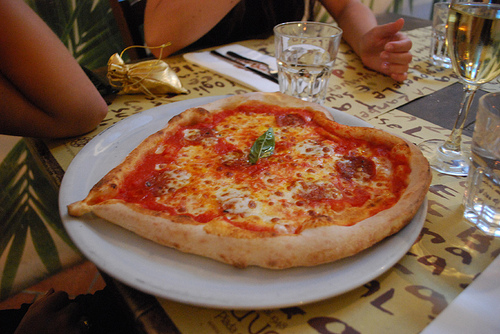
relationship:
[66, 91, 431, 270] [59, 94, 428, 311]
individual pizza on plate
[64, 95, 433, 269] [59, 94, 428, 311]
individual pizza on plate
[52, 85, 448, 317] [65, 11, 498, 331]
plate on top of table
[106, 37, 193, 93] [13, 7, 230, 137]
bag between arms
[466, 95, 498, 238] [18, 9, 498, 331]
glass on table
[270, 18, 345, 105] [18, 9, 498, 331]
glass on table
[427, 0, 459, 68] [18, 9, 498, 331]
glass on table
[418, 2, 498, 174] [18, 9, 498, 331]
glass on table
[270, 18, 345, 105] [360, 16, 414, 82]
glass on hand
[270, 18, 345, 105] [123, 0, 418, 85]
glass held by woman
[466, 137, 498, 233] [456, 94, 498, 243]
water in a glass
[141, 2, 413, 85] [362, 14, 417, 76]
person has a hand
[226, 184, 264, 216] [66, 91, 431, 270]
cheese on individual pizza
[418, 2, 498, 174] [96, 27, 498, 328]
glass on table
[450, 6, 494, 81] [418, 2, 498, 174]
wine in glass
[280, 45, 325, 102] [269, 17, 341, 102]
water in cup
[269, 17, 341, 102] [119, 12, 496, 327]
cup on table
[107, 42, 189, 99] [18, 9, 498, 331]
bag on table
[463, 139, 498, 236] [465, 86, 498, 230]
water in cup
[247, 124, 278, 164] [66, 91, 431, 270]
leaf on individual pizza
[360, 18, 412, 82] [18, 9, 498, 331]
hand on table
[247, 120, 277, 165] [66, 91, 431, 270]
oregano on individual pizza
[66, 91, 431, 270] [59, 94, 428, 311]
individual pizza on top of plate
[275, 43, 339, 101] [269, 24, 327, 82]
liquid in cup